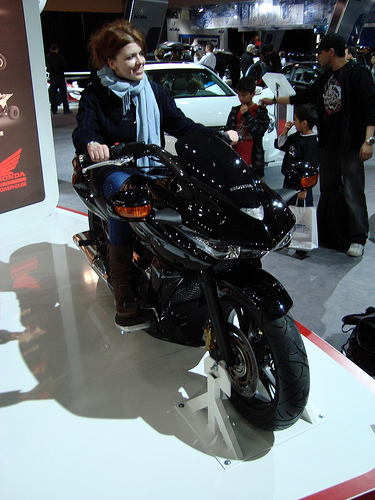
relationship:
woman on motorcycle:
[64, 33, 167, 148] [99, 130, 305, 312]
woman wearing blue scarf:
[64, 33, 167, 148] [104, 71, 155, 148]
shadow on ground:
[13, 249, 186, 474] [26, 214, 64, 240]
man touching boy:
[316, 30, 374, 252] [231, 84, 277, 168]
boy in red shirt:
[231, 84, 277, 168] [239, 138, 250, 161]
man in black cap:
[316, 30, 374, 252] [315, 30, 353, 62]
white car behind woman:
[156, 58, 238, 121] [64, 33, 167, 148]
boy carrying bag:
[231, 84, 277, 168] [226, 127, 254, 139]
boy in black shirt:
[284, 106, 322, 192] [294, 145, 317, 152]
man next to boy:
[316, 30, 374, 252] [231, 84, 277, 168]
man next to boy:
[316, 30, 374, 252] [284, 106, 322, 192]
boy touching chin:
[231, 84, 277, 168] [236, 97, 257, 112]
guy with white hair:
[244, 38, 269, 76] [242, 35, 265, 59]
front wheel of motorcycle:
[213, 282, 311, 438] [99, 130, 305, 312]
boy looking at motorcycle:
[231, 84, 277, 168] [99, 130, 305, 312]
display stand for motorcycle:
[178, 351, 257, 445] [99, 130, 305, 312]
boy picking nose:
[284, 106, 322, 192] [286, 121, 304, 132]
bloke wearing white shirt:
[198, 38, 221, 74] [197, 50, 224, 77]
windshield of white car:
[154, 68, 226, 96] [156, 58, 238, 121]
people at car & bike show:
[176, 34, 310, 89] [50, 15, 370, 214]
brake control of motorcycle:
[78, 146, 140, 164] [99, 130, 305, 312]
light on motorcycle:
[233, 195, 291, 227] [99, 130, 305, 312]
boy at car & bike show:
[231, 84, 277, 168] [50, 15, 370, 214]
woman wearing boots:
[64, 33, 167, 148] [93, 237, 146, 334]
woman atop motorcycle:
[64, 33, 167, 148] [99, 130, 305, 312]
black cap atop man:
[315, 30, 353, 62] [316, 30, 374, 252]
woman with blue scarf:
[64, 33, 167, 148] [104, 71, 155, 148]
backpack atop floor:
[326, 295, 375, 357] [327, 290, 374, 304]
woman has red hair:
[64, 33, 167, 148] [82, 14, 148, 43]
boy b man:
[231, 84, 277, 168] [316, 30, 374, 252]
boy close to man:
[284, 106, 322, 192] [316, 30, 374, 252]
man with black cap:
[316, 30, 374, 252] [315, 30, 353, 62]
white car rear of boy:
[156, 58, 238, 121] [231, 84, 277, 168]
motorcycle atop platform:
[99, 130, 305, 312] [73, 400, 172, 466]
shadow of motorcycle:
[13, 249, 186, 474] [99, 130, 305, 312]